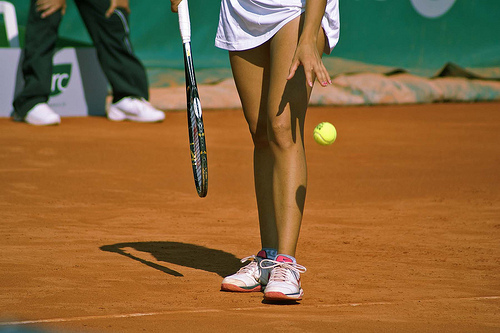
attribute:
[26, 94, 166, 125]
sneakers — white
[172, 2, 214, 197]
tennis racket — black, white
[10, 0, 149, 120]
pants — black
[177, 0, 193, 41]
handle — white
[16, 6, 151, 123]
trouser — black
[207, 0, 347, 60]
skirt — short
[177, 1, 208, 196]
tennis racket — black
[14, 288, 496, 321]
markings — white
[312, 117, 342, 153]
ball — bright yellow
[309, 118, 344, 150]
ball — small, green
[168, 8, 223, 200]
racket — black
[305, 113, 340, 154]
ball — yellow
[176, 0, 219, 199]
tennis racket — white and black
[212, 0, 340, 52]
skirt — white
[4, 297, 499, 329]
white line — long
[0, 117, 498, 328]
dirt — light brown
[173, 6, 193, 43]
handle — white